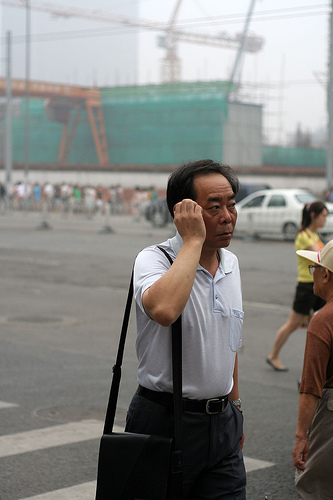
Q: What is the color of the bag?
A: Black.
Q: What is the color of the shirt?
A: White.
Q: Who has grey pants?
A: The man.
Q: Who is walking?
A: Man in grey pants.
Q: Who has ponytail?
A: Woman in back.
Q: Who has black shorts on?
A: Girl in yellow shirt.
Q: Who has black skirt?
A: Woman with yellow shirt.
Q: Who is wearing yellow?
A: Woman strolling.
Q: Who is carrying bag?
A: Man with hairline receding.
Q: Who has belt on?
A: Man on cell phone.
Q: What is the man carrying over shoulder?
A: Black case.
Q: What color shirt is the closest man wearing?
A: White.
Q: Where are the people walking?
A: Across the crosswalk.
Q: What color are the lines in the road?
A: White.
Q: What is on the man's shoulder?
A: A satchel.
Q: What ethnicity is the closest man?
A: Asian.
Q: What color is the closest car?
A: White.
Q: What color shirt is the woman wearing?
A: Yellow.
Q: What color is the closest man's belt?
A: Black.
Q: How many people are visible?
A: Three.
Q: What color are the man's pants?
A: Gray.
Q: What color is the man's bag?
A: Black.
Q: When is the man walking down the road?
A: Daytime.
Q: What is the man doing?
A: On cell phone.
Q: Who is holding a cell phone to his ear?
A: A man wearing a white shirt.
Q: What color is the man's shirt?
A: White.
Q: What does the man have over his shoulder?
A: Black bag.